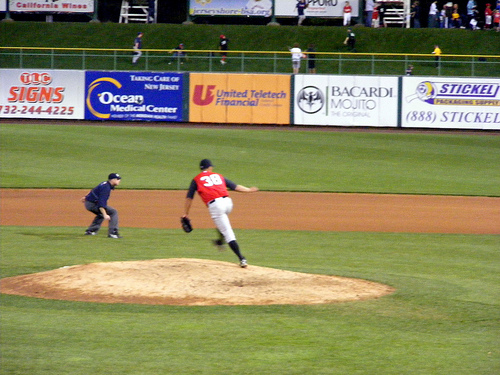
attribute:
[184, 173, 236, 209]
jersey — red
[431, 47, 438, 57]
jacket — yellow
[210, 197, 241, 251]
pants — white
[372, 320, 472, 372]
grass — short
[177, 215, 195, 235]
catcher glove — for catching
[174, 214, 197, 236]
glove — black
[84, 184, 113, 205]
shirt — blue